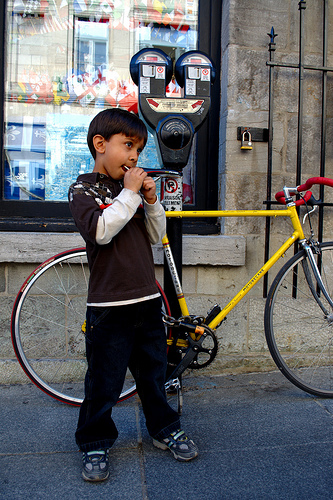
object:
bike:
[11, 177, 333, 405]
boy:
[67, 107, 199, 482]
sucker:
[123, 163, 129, 172]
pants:
[75, 309, 181, 452]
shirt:
[68, 172, 166, 306]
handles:
[274, 176, 333, 208]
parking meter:
[129, 46, 215, 169]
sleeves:
[69, 185, 142, 245]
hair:
[86, 108, 149, 160]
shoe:
[151, 428, 199, 461]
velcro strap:
[166, 428, 185, 446]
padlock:
[240, 130, 252, 150]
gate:
[263, 0, 331, 300]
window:
[0, 0, 223, 235]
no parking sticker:
[159, 175, 182, 212]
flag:
[74, 66, 103, 109]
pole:
[160, 169, 183, 393]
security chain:
[160, 310, 205, 326]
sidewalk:
[0, 365, 332, 498]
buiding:
[0, 0, 332, 384]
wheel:
[10, 246, 171, 407]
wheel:
[263, 241, 332, 400]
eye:
[122, 140, 134, 150]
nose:
[128, 147, 138, 163]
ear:
[92, 133, 105, 154]